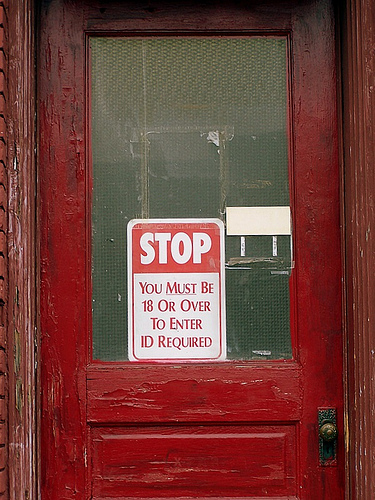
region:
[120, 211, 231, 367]
red and white sign on front of red door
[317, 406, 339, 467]
metal door knob on red wooden door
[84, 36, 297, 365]
glass pane on red wooden door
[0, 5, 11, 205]
red brick wall next to red wooden door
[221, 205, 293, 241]
plain white paper on glass door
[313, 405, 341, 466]
brass rectangular back plate behind door knob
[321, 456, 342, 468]
red paint overlap on brass plate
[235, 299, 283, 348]
patch of glass window on front of red door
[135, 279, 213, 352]
red lettering on front of white sign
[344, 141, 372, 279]
chipped wooden door frame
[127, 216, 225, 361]
A notice on the entrance.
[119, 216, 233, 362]
A notice pinned on the door.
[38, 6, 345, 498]
A notice pinned on the red door.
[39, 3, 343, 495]
An old red painted door.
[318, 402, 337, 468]
A metal handle of the old door.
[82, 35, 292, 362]
A window with a notice pinned on it.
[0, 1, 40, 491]
An old brown painted door frame.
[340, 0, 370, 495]
An old brown painted door frame.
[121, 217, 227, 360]
A notice written in red letters pinned on the door.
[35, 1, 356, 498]
An old door with notice on it.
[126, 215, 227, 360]
red and white sign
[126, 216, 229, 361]
red and white sign on door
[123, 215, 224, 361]
A sign letting you know you must be 18 to enter and ID is required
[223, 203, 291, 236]
plain white sign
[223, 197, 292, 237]
plain white sign on window of door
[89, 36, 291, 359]
window to door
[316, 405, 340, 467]
doorknob to the door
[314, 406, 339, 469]
brass doorknob on red door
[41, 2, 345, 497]
red, well worn door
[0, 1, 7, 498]
brick wall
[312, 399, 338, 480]
old fashioned door knob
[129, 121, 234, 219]
repaired spot on screen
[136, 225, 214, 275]
white STOP on red background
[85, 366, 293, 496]
cracked panels of a red door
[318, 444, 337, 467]
old fashioned key hole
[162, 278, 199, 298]
word that is underlined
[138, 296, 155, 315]
the number 18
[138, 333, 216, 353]
the words ID Required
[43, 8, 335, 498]
well worn red door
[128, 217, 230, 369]
sign prohibiting entry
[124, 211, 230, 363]
a red and white sign on the door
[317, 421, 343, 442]
a round metal door knob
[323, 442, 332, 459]
a key hole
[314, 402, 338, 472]
a metal door knob plate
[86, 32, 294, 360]
a window on the door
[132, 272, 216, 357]
red writing on the sign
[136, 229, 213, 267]
white writing on the sign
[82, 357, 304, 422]
a plank of wood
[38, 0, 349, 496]
a red wooden door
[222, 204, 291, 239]
a white sticker